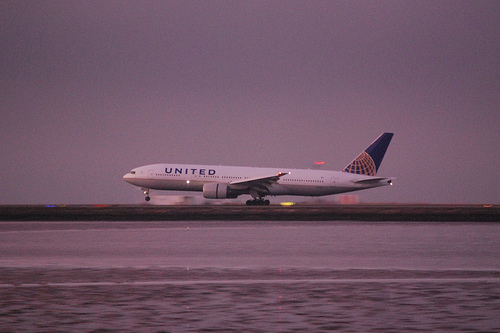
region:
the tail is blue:
[340, 102, 394, 169]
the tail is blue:
[360, 138, 407, 179]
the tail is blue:
[352, 105, 426, 216]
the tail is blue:
[360, 101, 404, 196]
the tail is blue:
[337, 48, 399, 209]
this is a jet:
[138, 150, 415, 192]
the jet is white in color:
[141, 167, 149, 186]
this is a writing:
[159, 166, 217, 183]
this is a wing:
[224, 170, 282, 193]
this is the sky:
[176, 40, 381, 121]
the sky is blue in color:
[291, 52, 308, 58]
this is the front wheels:
[138, 195, 156, 202]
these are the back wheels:
[238, 196, 268, 207]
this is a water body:
[240, 240, 434, 308]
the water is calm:
[228, 243, 314, 270]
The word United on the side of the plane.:
[161, 165, 232, 179]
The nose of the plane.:
[122, 171, 135, 186]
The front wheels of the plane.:
[141, 190, 155, 202]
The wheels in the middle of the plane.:
[239, 191, 274, 215]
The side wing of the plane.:
[224, 167, 286, 195]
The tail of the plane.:
[343, 120, 395, 176]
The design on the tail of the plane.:
[348, 148, 375, 175]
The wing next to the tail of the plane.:
[353, 175, 389, 191]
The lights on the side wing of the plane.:
[271, 167, 296, 177]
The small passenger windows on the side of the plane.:
[149, 171, 328, 183]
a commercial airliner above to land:
[88, 122, 480, 230]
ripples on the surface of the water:
[144, 280, 320, 330]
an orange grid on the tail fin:
[345, 154, 382, 179]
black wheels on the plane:
[248, 195, 274, 208]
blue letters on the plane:
[166, 156, 223, 182]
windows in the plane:
[284, 177, 323, 185]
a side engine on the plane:
[202, 179, 227, 199]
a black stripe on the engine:
[211, 181, 221, 198]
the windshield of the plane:
[126, 167, 138, 179]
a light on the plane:
[180, 173, 196, 190]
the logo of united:
[334, 108, 499, 182]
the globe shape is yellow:
[315, 68, 465, 228]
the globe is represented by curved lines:
[281, 85, 489, 280]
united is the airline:
[129, 122, 351, 298]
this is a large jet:
[53, 70, 495, 262]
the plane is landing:
[41, 92, 484, 269]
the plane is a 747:
[53, 72, 465, 270]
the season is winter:
[181, 237, 349, 292]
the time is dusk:
[42, 40, 450, 294]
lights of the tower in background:
[93, 98, 430, 255]